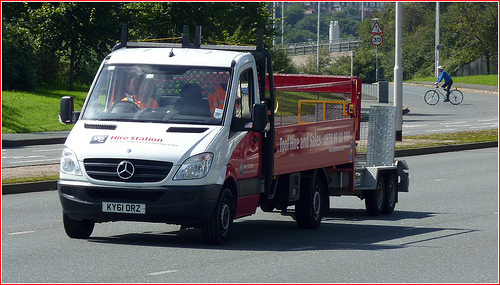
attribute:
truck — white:
[59, 42, 415, 236]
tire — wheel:
[204, 185, 238, 246]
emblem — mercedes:
[115, 159, 138, 179]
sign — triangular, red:
[369, 20, 392, 91]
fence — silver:
[279, 37, 364, 53]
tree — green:
[445, 4, 500, 77]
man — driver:
[110, 78, 160, 114]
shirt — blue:
[436, 72, 450, 85]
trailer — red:
[255, 71, 413, 227]